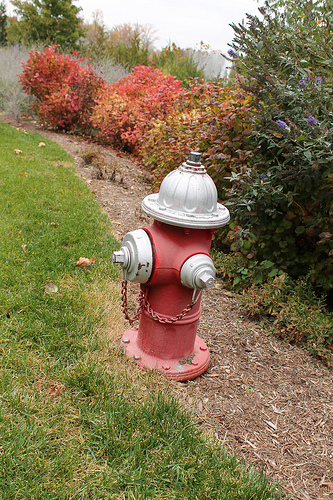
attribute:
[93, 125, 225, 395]
hydrant — white, red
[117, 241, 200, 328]
chains — red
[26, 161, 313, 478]
ground — bare, sloping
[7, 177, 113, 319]
grass — green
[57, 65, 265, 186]
bushes — red, tall, colorful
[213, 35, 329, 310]
bush — green, large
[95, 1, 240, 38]
sky — white, overcast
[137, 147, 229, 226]
cap — white, silver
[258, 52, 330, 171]
flowers — purple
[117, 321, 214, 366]
bolts — red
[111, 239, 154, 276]
knob — rusty, white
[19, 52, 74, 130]
leaves — red